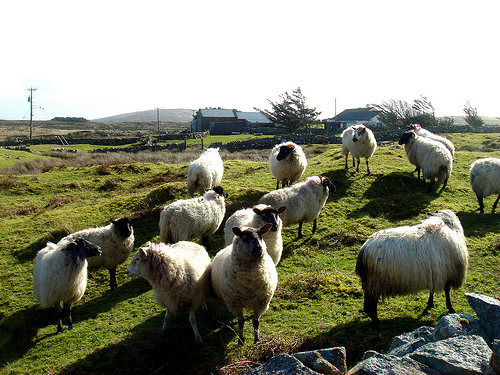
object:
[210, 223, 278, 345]
sheep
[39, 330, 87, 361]
grass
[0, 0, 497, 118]
sky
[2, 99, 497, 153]
distance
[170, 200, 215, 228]
fur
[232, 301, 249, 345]
legs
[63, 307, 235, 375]
shadows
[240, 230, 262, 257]
face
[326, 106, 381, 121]
roof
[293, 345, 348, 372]
rocks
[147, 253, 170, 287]
neck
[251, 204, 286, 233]
head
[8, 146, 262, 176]
thicket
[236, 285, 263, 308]
stomach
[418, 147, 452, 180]
edge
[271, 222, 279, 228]
nose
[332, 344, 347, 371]
edge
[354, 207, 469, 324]
sheep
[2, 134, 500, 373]
field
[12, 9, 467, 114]
day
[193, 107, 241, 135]
building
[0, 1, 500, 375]
background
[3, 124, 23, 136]
dirt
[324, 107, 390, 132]
house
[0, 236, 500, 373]
foreground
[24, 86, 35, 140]
pole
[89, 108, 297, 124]
mountain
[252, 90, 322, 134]
tree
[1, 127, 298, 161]
terrain